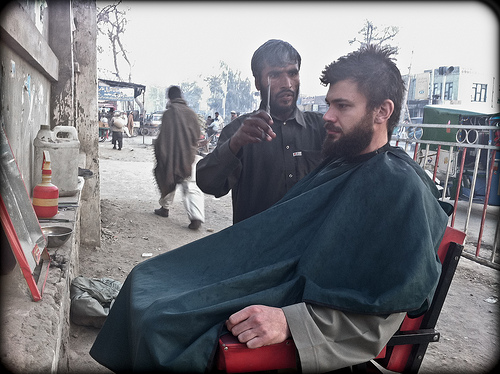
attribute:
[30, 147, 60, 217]
can — red, white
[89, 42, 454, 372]
man — getting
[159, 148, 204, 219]
pants — white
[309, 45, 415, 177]
man — sitting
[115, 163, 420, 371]
cape — green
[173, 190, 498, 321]
cloth — large, blue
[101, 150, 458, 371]
hair apron — green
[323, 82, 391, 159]
hair — facial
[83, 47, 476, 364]
man — sitting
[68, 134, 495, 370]
ground — dry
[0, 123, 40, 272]
mirror — small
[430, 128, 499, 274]
rails — grey and red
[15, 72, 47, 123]
woman — red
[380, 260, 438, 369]
chair — red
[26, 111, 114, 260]
can — white, gas can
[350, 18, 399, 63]
tree — leaf-filled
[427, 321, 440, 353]
bolt — metal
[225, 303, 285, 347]
hand — man's